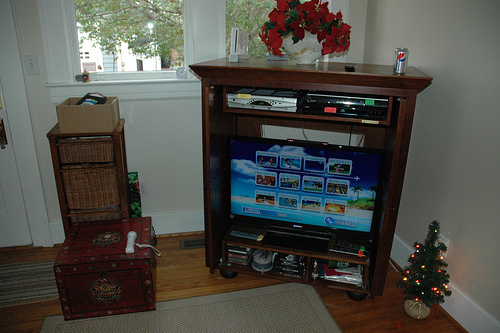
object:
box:
[53, 215, 159, 322]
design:
[89, 229, 124, 246]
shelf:
[45, 133, 134, 226]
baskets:
[56, 135, 114, 166]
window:
[35, 0, 351, 104]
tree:
[397, 218, 454, 321]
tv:
[217, 129, 397, 259]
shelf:
[225, 232, 372, 266]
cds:
[226, 243, 248, 250]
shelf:
[221, 263, 368, 293]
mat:
[0, 260, 60, 312]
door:
[0, 0, 36, 250]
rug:
[38, 281, 343, 332]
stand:
[185, 42, 437, 302]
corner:
[350, 0, 383, 66]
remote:
[124, 230, 140, 254]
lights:
[421, 264, 426, 269]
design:
[85, 269, 123, 309]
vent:
[178, 236, 206, 251]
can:
[392, 46, 410, 75]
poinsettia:
[253, 0, 352, 60]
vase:
[279, 28, 329, 65]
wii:
[227, 26, 249, 63]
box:
[223, 89, 302, 114]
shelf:
[226, 104, 391, 127]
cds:
[252, 252, 273, 265]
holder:
[250, 249, 278, 273]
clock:
[174, 66, 189, 80]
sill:
[75, 75, 201, 86]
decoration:
[73, 66, 91, 83]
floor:
[0, 230, 465, 333]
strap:
[134, 242, 162, 256]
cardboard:
[55, 91, 123, 136]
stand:
[263, 224, 336, 255]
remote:
[342, 62, 357, 73]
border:
[52, 256, 152, 269]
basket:
[62, 166, 121, 211]